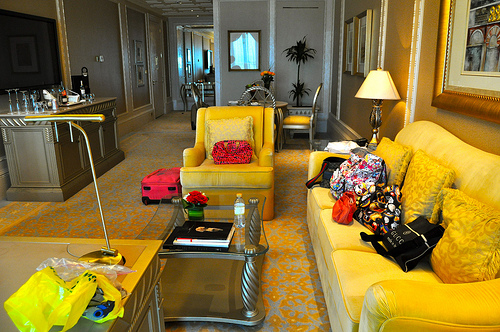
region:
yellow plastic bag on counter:
[1, 266, 128, 329]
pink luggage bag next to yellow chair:
[132, 160, 192, 207]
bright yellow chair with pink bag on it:
[176, 100, 280, 225]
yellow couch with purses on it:
[296, 116, 498, 327]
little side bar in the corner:
[2, 70, 130, 213]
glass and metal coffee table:
[121, 188, 271, 329]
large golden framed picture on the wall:
[428, 18, 498, 125]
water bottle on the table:
[230, 188, 246, 235]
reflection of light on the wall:
[383, 18, 425, 140]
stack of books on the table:
[159, 218, 239, 258]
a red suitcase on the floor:
[134, 162, 180, 201]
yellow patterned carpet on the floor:
[269, 136, 316, 329]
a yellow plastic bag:
[4, 267, 121, 330]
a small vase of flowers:
[177, 190, 225, 219]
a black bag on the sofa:
[357, 213, 442, 265]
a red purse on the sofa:
[331, 190, 354, 222]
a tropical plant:
[284, 36, 319, 100]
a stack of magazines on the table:
[171, 217, 240, 246]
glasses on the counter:
[11, 90, 38, 114]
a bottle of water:
[224, 188, 249, 225]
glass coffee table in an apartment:
[151, 186, 268, 318]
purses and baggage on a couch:
[320, 141, 430, 266]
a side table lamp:
[346, 67, 394, 148]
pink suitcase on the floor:
[136, 158, 183, 209]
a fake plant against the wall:
[280, 36, 316, 102]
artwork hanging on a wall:
[340, 12, 371, 78]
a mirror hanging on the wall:
[221, 21, 263, 77]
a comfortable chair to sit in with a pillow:
[181, 95, 281, 202]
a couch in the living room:
[298, 118, 497, 324]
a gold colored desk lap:
[18, 108, 125, 268]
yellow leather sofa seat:
[301, 120, 496, 330]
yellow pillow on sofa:
[377, 138, 411, 186]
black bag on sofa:
[363, 213, 446, 268]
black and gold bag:
[360, 182, 402, 233]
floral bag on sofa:
[333, 150, 387, 193]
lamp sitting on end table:
[352, 69, 399, 144]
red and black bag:
[212, 139, 252, 166]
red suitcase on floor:
[139, 165, 181, 205]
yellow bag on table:
[6, 265, 125, 330]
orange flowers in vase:
[258, 69, 273, 94]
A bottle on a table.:
[231, 188, 248, 230]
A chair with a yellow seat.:
[280, 82, 325, 147]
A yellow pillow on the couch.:
[424, 184, 499, 284]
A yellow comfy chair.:
[179, 103, 278, 220]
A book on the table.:
[171, 218, 236, 250]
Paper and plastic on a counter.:
[2, 253, 138, 330]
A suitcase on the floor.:
[138, 160, 180, 205]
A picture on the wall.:
[429, 0, 499, 124]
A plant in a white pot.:
[279, 32, 319, 139]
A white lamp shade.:
[353, 64, 402, 101]